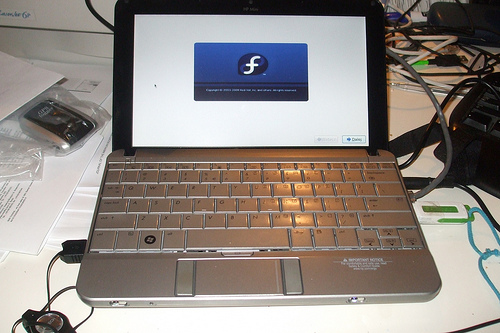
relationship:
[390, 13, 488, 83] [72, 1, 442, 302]
wires in back of laptop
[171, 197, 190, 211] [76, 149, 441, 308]
key on keyboard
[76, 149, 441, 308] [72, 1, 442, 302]
keyboard of laptop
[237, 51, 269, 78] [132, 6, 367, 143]
'f' on screen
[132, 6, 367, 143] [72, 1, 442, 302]
screen of laptop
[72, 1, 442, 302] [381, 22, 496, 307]
laptop sitting on table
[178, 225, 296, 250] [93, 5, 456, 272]
space bar on laptop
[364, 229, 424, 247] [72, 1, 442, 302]
arrow keys on laptop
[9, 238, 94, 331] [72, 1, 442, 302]
something plugged into laptop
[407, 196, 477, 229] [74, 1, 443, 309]
flash drive plugged into laptop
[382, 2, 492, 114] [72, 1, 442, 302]
wires behind laptop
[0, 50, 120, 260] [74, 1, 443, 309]
papers sit next to laptop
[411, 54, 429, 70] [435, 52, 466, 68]
marker on usb cable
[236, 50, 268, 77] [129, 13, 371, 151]
logo on screen